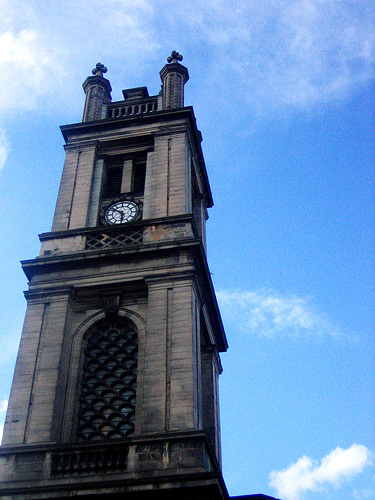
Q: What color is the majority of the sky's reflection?
A: Blue.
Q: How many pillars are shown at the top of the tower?
A: Two.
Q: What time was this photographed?
A: 6:50.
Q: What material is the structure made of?
A: Stone.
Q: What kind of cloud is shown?
A: Alto cumulus.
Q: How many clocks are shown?
A: One.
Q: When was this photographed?
A: Day time.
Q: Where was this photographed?
A: Church.